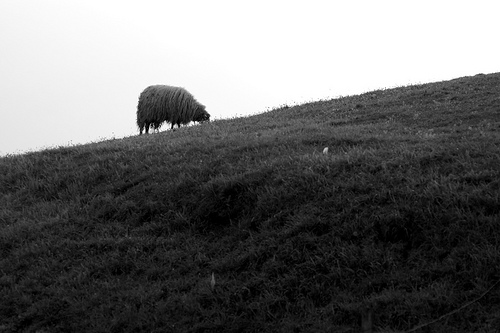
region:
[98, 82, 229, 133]
A sheep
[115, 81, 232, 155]
A hairy sheep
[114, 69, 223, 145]
A hairy sheep on a hill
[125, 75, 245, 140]
A hairy sheep eating grass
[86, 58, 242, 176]
A hairy sheep eating grass on a hill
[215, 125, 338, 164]
Short grass on a hill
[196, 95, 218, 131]
The head of a hairy sheep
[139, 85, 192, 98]
The back of a hairy sheep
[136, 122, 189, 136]
The legs of a hairy sheep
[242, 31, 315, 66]
The sky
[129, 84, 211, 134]
lone sheep is grazing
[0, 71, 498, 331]
Grassy hill sloping up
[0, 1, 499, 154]
The sky is clear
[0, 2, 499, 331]
The shot is black and white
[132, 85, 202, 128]
The sheep has four legs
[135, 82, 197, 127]
The sheep has long hair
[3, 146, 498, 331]
The grass is tall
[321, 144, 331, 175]
white flower on the hill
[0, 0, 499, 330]
The scene is daytime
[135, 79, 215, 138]
The sheep is a black sheep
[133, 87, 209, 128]
this is a sheep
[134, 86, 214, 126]
the wool is rugged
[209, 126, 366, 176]
this is a grass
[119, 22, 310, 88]
this is the sky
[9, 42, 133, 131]
the sky is clear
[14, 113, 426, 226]
the ground is raised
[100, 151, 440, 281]
the ground is grey in color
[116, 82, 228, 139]
the sheep is eating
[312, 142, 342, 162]
the grass has a white item on it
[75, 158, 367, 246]
the grass is grey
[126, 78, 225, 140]
gray sheep grazing in black and white photo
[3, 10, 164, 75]
white sky in black and white photo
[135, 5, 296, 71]
white sky in black and white photo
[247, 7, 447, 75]
white sky in black and white photo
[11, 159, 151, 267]
gray grass in black and white photo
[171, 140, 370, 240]
gray grass in black and white photo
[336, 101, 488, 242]
gray grass in black and white photo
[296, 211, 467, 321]
gray grass in black and white photo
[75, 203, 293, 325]
gray grass in black and white photo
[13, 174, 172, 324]
gray grass in black and white photo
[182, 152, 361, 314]
this is the grass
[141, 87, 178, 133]
the wool is rugged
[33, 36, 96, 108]
this is the sky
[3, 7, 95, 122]
the sky is clear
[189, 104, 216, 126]
the sheep is feeding on grass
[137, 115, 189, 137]
the sheep has four legs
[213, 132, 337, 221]
the grass is long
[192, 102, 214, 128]
the sheep's head is bent downwards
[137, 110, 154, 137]
the hind legs are apart